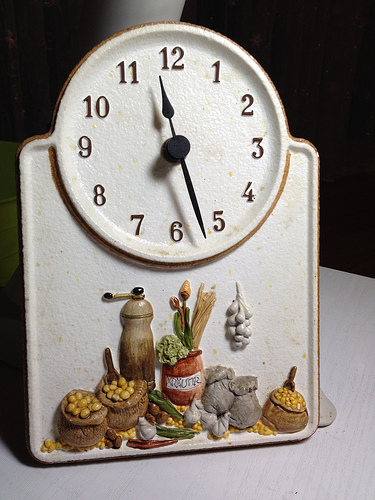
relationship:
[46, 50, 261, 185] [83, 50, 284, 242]
clock has face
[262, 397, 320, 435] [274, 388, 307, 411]
bag has food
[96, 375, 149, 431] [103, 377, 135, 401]
bag has food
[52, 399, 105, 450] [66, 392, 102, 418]
bag has food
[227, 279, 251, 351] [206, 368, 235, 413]
garlic above sack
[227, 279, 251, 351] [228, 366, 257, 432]
garlic above sack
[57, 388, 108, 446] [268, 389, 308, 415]
bag contains food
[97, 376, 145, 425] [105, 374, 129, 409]
bag contains food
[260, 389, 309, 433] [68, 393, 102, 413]
bag contains food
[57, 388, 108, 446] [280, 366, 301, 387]
bag contains spoon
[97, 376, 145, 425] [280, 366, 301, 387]
bag contains spoon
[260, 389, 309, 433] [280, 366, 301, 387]
bag contains spoon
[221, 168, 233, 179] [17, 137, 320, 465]
speck across panel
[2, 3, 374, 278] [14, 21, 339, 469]
form behind clock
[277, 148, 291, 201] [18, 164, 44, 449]
trim along edge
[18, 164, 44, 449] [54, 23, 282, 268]
edge on clock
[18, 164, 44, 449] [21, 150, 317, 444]
edge on panel